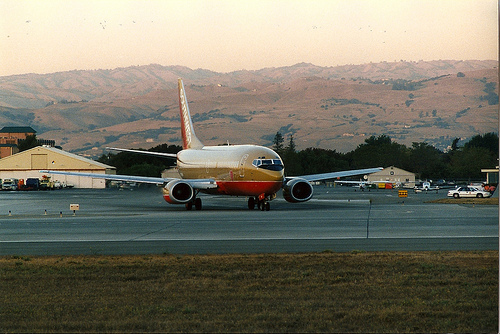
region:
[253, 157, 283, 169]
the cockpit windows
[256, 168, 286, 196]
the nose of the plane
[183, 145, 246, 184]
the fuselage of the plane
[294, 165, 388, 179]
a wing on the plane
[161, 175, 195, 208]
an engine on the plane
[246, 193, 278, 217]
the wheels on the plane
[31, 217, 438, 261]
an airport runway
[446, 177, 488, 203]
a car parked at the airport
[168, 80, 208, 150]
name of the airline that operates plane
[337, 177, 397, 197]
small private plane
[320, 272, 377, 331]
grass on the ground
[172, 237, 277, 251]
cement pavement on the ground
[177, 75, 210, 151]
tail on the airplane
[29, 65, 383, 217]
yellow and red plane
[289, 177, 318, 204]
left engine propellor on plane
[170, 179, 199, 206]
right engine propellor on plane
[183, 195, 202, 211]
black wheels on plane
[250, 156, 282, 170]
windshield on the planle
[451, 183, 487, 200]
white car parked in lot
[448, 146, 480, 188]
tall trees in the background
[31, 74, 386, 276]
a plane in the runway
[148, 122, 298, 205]
the plane is bronze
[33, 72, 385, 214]
A plane is parked on a runway.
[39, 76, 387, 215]
A plane is sitting on a runway.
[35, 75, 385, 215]
A plane's colors are red, brown, black, and blue.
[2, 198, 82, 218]
Four objects are attached to the ground.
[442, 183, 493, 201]
A car is in the background.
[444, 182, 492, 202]
The colors of a car are white and black.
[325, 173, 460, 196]
Two airplanes are in the background.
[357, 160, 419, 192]
A building is in the background.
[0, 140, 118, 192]
A building is behind a plane.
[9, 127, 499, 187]
Trees are in the background.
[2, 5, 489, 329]
jet airplane at an airport near mountains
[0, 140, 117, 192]
white and tan building at an airport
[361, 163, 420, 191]
tan building at an airport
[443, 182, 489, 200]
white car parked at an airport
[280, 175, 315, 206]
engine of a jet airplane at an airport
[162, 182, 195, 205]
engine of a jet airplane at an airport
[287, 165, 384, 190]
left wing of a jet airplane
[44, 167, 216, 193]
right wing of a jet airplane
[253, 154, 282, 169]
cockpit area of a jet airplane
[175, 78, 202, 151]
red and gold tail of a jet airplane